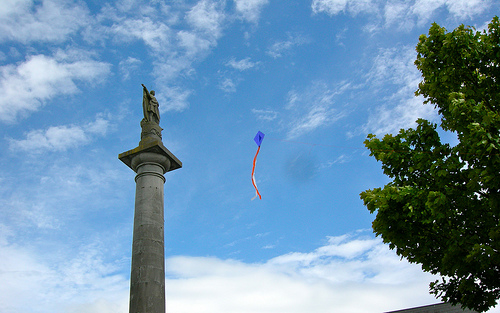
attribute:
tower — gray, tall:
[122, 84, 188, 309]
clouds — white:
[6, 7, 219, 134]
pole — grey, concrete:
[104, 99, 195, 310]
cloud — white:
[174, 233, 450, 312]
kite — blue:
[244, 128, 264, 200]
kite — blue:
[242, 116, 287, 221]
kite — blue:
[245, 125, 270, 198]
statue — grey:
[131, 78, 170, 153]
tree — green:
[364, 20, 499, 242]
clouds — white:
[277, 236, 329, 278]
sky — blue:
[280, 172, 336, 212]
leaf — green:
[377, 192, 385, 199]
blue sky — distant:
[287, 136, 337, 180]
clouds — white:
[2, 2, 498, 307]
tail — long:
[247, 141, 263, 203]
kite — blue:
[246, 127, 268, 204]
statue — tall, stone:
[138, 79, 165, 147]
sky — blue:
[0, 0, 499, 310]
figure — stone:
[128, 92, 174, 154]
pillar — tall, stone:
[132, 158, 167, 311]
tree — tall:
[362, 14, 485, 307]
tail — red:
[249, 146, 265, 198]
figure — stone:
[139, 85, 161, 131]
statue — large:
[136, 87, 170, 167]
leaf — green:
[390, 146, 400, 157]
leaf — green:
[374, 148, 384, 158]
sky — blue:
[2, 8, 401, 74]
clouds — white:
[13, 237, 111, 312]